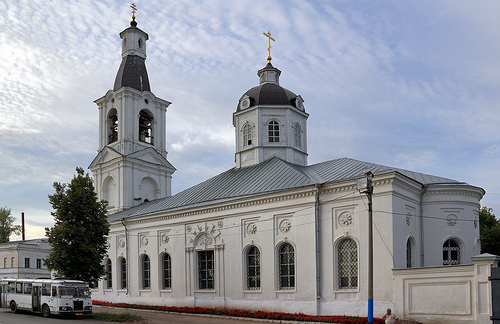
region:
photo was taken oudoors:
[1, 1, 499, 317]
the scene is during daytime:
[1, 1, 498, 321]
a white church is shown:
[86, 13, 491, 315]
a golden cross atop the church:
[258, 28, 278, 61]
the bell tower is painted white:
[93, 90, 176, 208]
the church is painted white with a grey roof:
[86, 4, 488, 322]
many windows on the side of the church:
[91, 232, 391, 321]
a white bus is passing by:
[3, 276, 96, 320]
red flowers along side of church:
[92, 292, 375, 321]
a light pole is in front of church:
[352, 169, 385, 322]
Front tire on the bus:
[34, 301, 56, 318]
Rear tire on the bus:
[5, 298, 22, 314]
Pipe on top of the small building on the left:
[18, 208, 30, 243]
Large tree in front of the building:
[50, 166, 115, 275]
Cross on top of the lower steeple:
[259, 26, 282, 66]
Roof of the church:
[222, 173, 299, 193]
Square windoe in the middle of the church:
[189, 240, 221, 302]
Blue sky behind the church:
[322, 21, 464, 111]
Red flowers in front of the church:
[173, 306, 275, 320]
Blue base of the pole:
[362, 296, 382, 322]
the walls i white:
[99, 173, 496, 265]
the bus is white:
[8, 274, 111, 322]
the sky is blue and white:
[342, 39, 452, 124]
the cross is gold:
[247, 20, 284, 58]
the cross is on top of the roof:
[241, 20, 300, 71]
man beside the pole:
[379, 305, 400, 322]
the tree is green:
[44, 174, 134, 311]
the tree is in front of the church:
[56, 166, 134, 308]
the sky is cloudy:
[11, 15, 97, 123]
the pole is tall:
[354, 170, 374, 320]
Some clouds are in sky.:
[22, 19, 87, 136]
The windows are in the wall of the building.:
[106, 253, 368, 303]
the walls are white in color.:
[136, 219, 365, 322]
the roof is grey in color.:
[193, 173, 300, 192]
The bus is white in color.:
[4, 274, 96, 318]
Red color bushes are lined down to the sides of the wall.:
[96, 295, 319, 322]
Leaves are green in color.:
[58, 177, 120, 274]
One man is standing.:
[381, 306, 406, 321]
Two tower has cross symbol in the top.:
[107, 4, 283, 78]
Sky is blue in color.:
[351, 57, 473, 134]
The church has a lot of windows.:
[193, 248, 365, 292]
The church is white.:
[112, 124, 479, 321]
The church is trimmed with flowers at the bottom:
[93, 295, 390, 319]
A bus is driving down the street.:
[9, 277, 107, 319]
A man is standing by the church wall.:
[382, 300, 411, 322]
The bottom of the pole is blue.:
[363, 280, 387, 320]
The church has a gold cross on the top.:
[253, 30, 295, 78]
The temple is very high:
[104, 29, 207, 167]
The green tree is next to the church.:
[58, 178, 115, 302]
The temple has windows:
[238, 111, 333, 166]